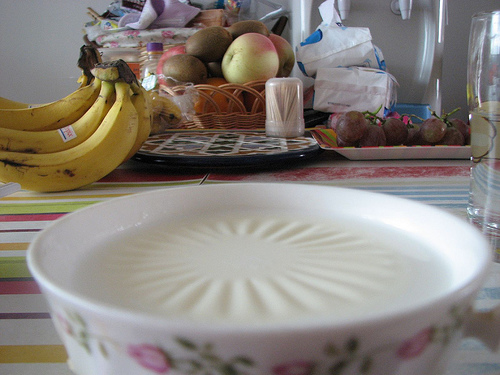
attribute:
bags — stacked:
[287, 3, 402, 125]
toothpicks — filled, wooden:
[267, 83, 301, 124]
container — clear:
[263, 75, 307, 139]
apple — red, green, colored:
[217, 29, 285, 93]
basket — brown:
[116, 79, 305, 131]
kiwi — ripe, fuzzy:
[160, 49, 211, 90]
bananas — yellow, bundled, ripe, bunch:
[1, 59, 150, 194]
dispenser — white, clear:
[17, 177, 492, 374]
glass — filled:
[456, 7, 498, 242]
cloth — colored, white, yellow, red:
[394, 166, 444, 202]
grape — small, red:
[332, 109, 375, 142]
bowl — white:
[17, 176, 498, 371]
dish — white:
[23, 187, 490, 370]